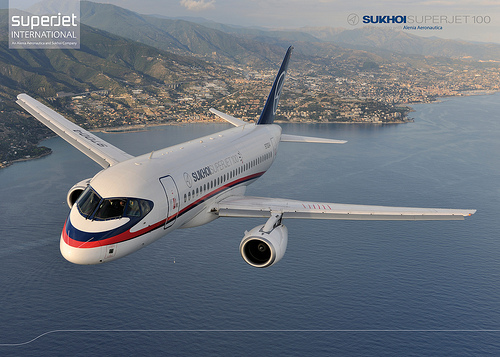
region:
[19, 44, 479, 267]
white plane flying above water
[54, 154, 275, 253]
red and blue strips on plane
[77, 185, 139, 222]
front windows of plane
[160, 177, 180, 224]
door on side of plane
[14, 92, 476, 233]
white wings of airplane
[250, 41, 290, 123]
blue tail fin of plane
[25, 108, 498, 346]
water plane is flying over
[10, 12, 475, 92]
mountains beside water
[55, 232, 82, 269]
nose of white airplane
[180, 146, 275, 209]
row of windows on side of plane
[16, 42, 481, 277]
a plane in the air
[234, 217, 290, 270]
the engine of a plane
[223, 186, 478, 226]
a wing of a plane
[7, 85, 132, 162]
a wing of a plane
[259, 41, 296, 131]
the tail of a plane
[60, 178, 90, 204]
an engine of a plane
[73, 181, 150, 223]
the front window of a plane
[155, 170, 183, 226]
the door of a plane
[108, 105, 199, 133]
the shore lin of the ocean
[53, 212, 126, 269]
the nose of a plane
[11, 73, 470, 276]
white passenger plane in the air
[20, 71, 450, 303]
airplane flying over ocean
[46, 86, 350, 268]
white plane with red and blue stripes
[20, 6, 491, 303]
advertisement for superjet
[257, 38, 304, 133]
blue tail of airplane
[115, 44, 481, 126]
city in the distance behind plane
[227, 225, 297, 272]
propeller of airplane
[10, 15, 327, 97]
mountains in the distance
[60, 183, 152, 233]
airplane pilot's windows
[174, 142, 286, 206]
rows of passengers windows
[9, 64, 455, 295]
airplane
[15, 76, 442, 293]
white airplane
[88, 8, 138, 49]
white clouds in blue sky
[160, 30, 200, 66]
white clouds in blue sky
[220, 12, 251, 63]
white clouds in blue sky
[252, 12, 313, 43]
white clouds in blue sky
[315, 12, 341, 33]
white clouds in blue sky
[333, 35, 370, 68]
white clouds in blue sky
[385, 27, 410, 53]
white clouds in blue sky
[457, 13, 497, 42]
white clouds in blue sky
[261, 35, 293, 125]
The tail of the plane.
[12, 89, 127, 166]
The left large side wing of the plane.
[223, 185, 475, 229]
The large right side wing of the plane.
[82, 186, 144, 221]
The front window of the plane.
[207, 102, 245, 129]
The small left wing near the tail of the plane.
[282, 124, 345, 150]
The small right wing near the tail of the plane.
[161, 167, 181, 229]
The door on the side of the plane.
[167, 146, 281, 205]
The passenger windows on the side of the plane.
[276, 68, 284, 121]
The design on the tail of the plane.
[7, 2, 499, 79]
The mountains in the distance.